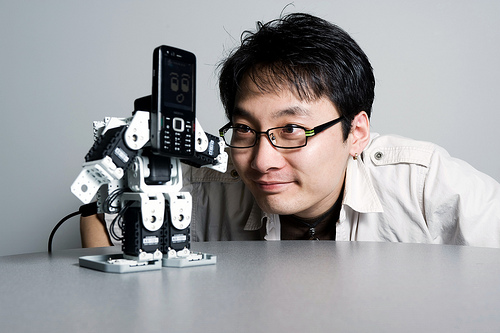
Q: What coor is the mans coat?
A: White.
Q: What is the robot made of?
A: Phones.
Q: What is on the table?
A: Robot.